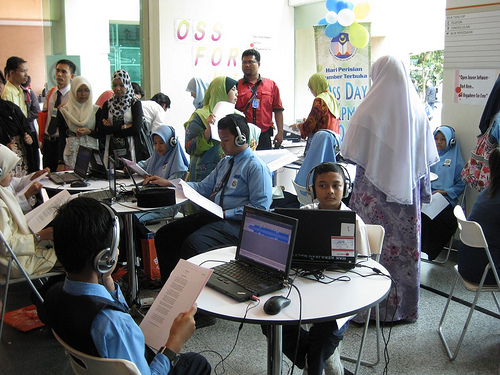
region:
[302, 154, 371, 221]
Headphones on child's head.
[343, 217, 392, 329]
Boy sitting on white chair.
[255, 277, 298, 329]
Black computer mouse on table.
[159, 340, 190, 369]
Black watch on person's wrist.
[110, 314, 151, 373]
Person wearing blue shirt.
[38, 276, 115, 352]
Person wearing dark vest.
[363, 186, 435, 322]
Person wearing floral printed dress.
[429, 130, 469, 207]
Woman has on blue head covering.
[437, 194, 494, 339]
Person sitting in white chair.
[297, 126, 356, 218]
Person wearing blue head covering.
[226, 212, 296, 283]
laptop on the table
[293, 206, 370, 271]
laptop on the table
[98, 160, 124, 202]
laptop on the table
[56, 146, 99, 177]
laptop on the table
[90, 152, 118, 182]
laptop on the table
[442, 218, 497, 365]
chair on the floor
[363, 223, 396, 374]
chair on the floor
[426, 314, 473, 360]
base of the chair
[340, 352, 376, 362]
base of the chair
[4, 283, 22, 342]
base of the chair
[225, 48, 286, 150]
A man in a red shirt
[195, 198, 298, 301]
A black laptop computer on the table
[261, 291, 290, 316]
A small black computer mouse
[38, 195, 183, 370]
A boy in a sweater vest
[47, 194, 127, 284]
A boy wearing headphones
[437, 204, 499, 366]
Part of a small folding chair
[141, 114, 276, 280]
A boy wearing a blue shirt and tie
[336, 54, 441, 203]
A woman with a white head covering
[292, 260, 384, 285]
Cables on the table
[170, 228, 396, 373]
A small round table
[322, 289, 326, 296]
part of a table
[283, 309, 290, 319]
edge of a table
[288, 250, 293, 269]
part of a laptop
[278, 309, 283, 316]
part of a mouse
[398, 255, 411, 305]
part of a clothe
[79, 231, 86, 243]
head of a boy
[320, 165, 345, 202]
face of a boy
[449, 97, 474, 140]
part of a wall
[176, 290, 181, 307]
part of a paper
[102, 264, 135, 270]
part of an ear phone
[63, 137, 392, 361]
Kids sitting inside the classroom.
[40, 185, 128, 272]
The boy have headphones over his ear.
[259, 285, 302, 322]
A black mouse on the table.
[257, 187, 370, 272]
A laptop in front of the little boy.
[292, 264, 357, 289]
Cords from the laptop on the table.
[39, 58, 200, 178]
People are standing in the room.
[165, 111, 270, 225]
The boy is reading the book.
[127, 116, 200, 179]
The little girl is sitting in the chair.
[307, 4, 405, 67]
Balloons attached to the wall.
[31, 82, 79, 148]
The man is wearing a tie.